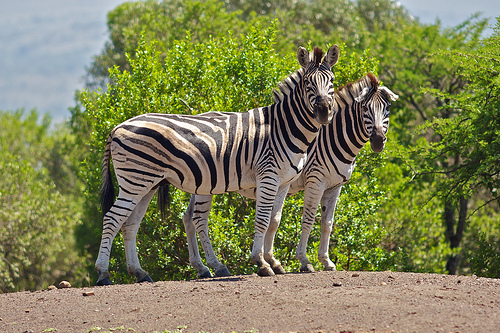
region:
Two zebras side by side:
[95, 39, 396, 277]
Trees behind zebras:
[2, 2, 496, 277]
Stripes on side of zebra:
[152, 121, 271, 170]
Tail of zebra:
[92, 131, 116, 213]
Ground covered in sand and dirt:
[0, 270, 498, 328]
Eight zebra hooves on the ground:
[92, 260, 347, 285]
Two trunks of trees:
[435, 173, 471, 281]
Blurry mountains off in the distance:
[2, 0, 103, 123]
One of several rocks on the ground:
[82, 289, 94, 296]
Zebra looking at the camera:
[289, 39, 342, 128]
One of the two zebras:
[95, 46, 338, 285]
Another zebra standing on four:
[182, 72, 396, 276]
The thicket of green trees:
[0, 0, 498, 294]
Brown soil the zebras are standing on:
[0, 272, 497, 332]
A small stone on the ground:
[57, 280, 71, 289]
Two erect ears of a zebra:
[297, 44, 339, 69]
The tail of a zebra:
[98, 130, 114, 215]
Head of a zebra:
[297, 45, 339, 125]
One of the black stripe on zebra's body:
[222, 112, 237, 191]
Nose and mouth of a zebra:
[312, 100, 334, 125]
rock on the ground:
[56, 274, 78, 294]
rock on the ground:
[79, 290, 100, 306]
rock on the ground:
[32, 292, 44, 307]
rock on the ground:
[20, 307, 39, 314]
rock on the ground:
[152, 276, 172, 288]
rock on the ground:
[214, 276, 241, 303]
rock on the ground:
[259, 278, 291, 294]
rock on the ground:
[324, 268, 356, 295]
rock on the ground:
[346, 270, 365, 284]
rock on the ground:
[377, 268, 402, 286]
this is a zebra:
[105, 39, 351, 289]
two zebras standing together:
[69, 27, 431, 292]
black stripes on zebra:
[129, 104, 250, 198]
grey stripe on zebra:
[119, 125, 179, 168]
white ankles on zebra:
[93, 252, 163, 279]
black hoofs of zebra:
[78, 264, 180, 294]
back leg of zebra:
[93, 173, 148, 281]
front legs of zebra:
[245, 170, 297, 276]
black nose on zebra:
[311, 90, 337, 127]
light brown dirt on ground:
[2, 230, 482, 331]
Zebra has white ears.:
[287, 45, 353, 70]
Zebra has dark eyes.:
[296, 74, 338, 85]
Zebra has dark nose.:
[311, 93, 342, 135]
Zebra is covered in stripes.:
[150, 135, 224, 171]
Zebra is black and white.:
[159, 105, 244, 179]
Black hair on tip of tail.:
[158, 182, 168, 209]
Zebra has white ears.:
[356, 79, 401, 106]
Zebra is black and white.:
[329, 120, 356, 165]